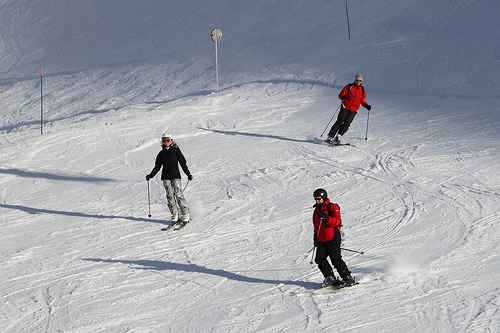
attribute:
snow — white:
[409, 20, 473, 148]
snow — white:
[1, 0, 497, 322]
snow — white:
[72, 236, 108, 293]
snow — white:
[378, 228, 433, 278]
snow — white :
[88, 96, 116, 113]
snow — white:
[422, 150, 453, 232]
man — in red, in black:
[324, 74, 370, 144]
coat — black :
[149, 144, 191, 179]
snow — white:
[223, 82, 275, 137]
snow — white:
[443, 206, 497, 234]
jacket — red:
[319, 197, 369, 254]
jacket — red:
[338, 84, 367, 111]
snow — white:
[357, 159, 448, 231]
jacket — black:
[143, 144, 192, 178]